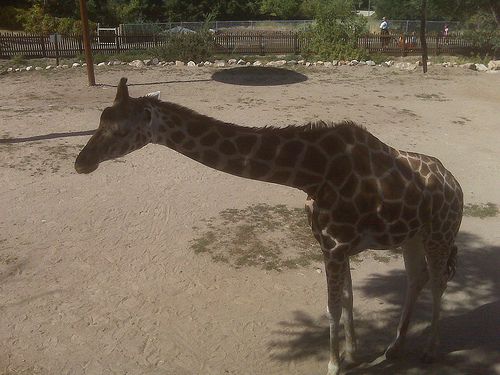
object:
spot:
[200, 132, 220, 147]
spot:
[235, 135, 257, 155]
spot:
[326, 155, 353, 188]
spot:
[408, 218, 421, 229]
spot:
[440, 220, 452, 233]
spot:
[339, 173, 360, 199]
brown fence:
[0, 31, 497, 65]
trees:
[58, 15, 95, 57]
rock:
[324, 62, 332, 68]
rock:
[297, 59, 306, 65]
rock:
[305, 62, 310, 67]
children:
[410, 35, 417, 48]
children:
[398, 34, 407, 47]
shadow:
[268, 231, 500, 375]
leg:
[396, 240, 429, 343]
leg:
[424, 244, 448, 343]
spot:
[301, 146, 328, 176]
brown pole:
[78, 0, 96, 86]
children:
[442, 26, 449, 46]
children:
[404, 35, 412, 48]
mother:
[379, 17, 390, 49]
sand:
[7, 49, 496, 367]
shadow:
[101, 66, 308, 87]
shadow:
[0, 130, 99, 144]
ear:
[113, 77, 129, 104]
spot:
[219, 141, 237, 156]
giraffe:
[75, 76, 464, 375]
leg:
[321, 245, 346, 356]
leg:
[341, 255, 356, 353]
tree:
[417, 8, 429, 73]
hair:
[132, 96, 364, 135]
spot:
[357, 214, 386, 233]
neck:
[150, 97, 318, 191]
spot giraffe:
[331, 244, 352, 262]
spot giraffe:
[267, 170, 289, 184]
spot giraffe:
[215, 125, 237, 138]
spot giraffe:
[170, 131, 186, 144]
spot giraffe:
[444, 231, 453, 243]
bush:
[295, 18, 369, 62]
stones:
[35, 67, 43, 71]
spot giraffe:
[254, 134, 280, 160]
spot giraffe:
[313, 183, 337, 210]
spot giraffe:
[404, 183, 422, 206]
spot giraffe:
[311, 209, 331, 230]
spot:
[377, 168, 406, 199]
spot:
[351, 144, 373, 177]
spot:
[413, 171, 426, 191]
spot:
[431, 193, 445, 215]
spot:
[431, 214, 443, 233]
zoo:
[0, 28, 498, 373]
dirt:
[0, 266, 500, 373]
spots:
[201, 150, 220, 169]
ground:
[6, 68, 498, 369]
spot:
[377, 201, 403, 224]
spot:
[371, 152, 394, 177]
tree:
[14, 4, 63, 56]